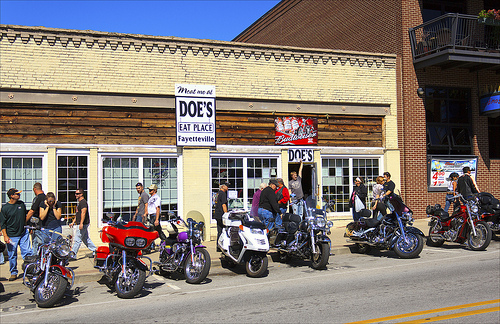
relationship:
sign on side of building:
[174, 83, 219, 149] [0, 24, 403, 249]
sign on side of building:
[274, 114, 321, 146] [0, 24, 403, 249]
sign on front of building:
[174, 83, 219, 149] [0, 24, 403, 249]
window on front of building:
[101, 153, 180, 222] [0, 24, 403, 249]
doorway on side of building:
[289, 161, 317, 230] [0, 24, 403, 249]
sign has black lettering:
[174, 83, 219, 149] [178, 100, 214, 146]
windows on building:
[212, 154, 391, 218] [0, 24, 403, 249]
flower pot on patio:
[477, 9, 499, 25] [407, 13, 499, 74]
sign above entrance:
[274, 114, 321, 146] [289, 161, 317, 230]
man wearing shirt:
[145, 184, 171, 248] [145, 194, 162, 217]